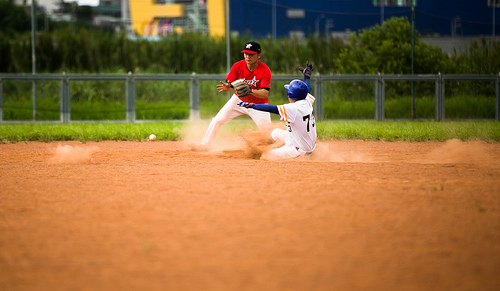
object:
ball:
[147, 135, 156, 142]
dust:
[166, 114, 206, 141]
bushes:
[333, 34, 457, 104]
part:
[198, 6, 224, 32]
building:
[158, 12, 223, 30]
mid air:
[110, 51, 235, 159]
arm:
[250, 103, 283, 113]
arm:
[300, 70, 316, 104]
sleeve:
[261, 85, 270, 92]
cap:
[235, 39, 262, 63]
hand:
[213, 80, 233, 94]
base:
[187, 112, 287, 181]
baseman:
[196, 36, 282, 160]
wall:
[62, 50, 152, 121]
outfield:
[58, 29, 439, 283]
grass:
[390, 112, 454, 144]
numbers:
[297, 114, 315, 135]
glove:
[231, 79, 253, 98]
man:
[236, 61, 319, 159]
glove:
[300, 60, 313, 78]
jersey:
[226, 60, 267, 100]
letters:
[248, 80, 262, 90]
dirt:
[237, 197, 265, 215]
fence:
[5, 71, 483, 124]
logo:
[244, 43, 252, 49]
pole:
[27, 68, 42, 117]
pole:
[364, 71, 390, 123]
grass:
[342, 115, 374, 140]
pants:
[200, 92, 272, 148]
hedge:
[334, 37, 391, 70]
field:
[2, 131, 484, 264]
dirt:
[0, 139, 36, 160]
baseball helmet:
[284, 79, 307, 97]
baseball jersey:
[275, 94, 317, 149]